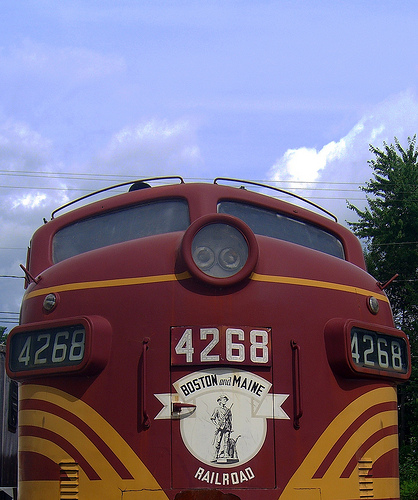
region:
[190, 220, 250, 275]
the headlight of a train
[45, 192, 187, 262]
the window on a train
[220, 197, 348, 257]
the window on a train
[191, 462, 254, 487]
a word written in white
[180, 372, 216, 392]
a word written in black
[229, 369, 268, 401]
a word written in black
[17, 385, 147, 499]
some yellow painting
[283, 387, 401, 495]
some yellow painting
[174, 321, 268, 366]
some white numbers on a train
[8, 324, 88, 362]
some white numbers on a train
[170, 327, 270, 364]
white print on the burgundy colored train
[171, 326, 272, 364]
white print on the train reading 4268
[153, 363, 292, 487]
black and white logo on the train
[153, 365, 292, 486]
Boston and Maine Railroad logo on the train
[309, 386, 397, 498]
Yellow design on the burgundy train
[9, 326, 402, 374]
The number 4268 printed three times on the train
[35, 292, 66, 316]
light on the train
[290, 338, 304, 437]
burgundy train handle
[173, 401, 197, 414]
handle on the train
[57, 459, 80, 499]
a bunch of yellow vents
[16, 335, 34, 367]
a number 4 written in white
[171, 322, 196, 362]
a number 4 written in white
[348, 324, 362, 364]
a number 4 written in white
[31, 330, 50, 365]
a number 2 written in white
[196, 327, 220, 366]
a number 2 written in white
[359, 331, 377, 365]
a number 2 written in white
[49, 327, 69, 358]
a number 6 written in white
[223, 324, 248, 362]
a number 6 written in white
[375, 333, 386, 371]
a number 6 written in white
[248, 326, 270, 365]
a number 8 written in white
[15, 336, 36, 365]
a number 4 on a train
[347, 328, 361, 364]
a number 4 on a train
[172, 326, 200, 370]
a number 4 on a train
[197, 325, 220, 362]
a number 2 on a train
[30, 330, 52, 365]
a number 2 on a train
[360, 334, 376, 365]
a number 2 on a train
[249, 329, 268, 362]
a number 8 on a train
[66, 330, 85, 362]
a number 8 on a train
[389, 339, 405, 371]
a number 8 on a train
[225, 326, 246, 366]
a number 6 on a train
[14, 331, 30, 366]
a number 4 written in white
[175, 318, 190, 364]
a number 4 written in white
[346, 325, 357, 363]
a number 4 written in white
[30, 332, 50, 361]
a number 2 written in white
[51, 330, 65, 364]
a number 6 written in white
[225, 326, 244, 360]
a number 6 written in white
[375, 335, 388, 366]
a number 6 written in white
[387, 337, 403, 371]
a number 8 written in white